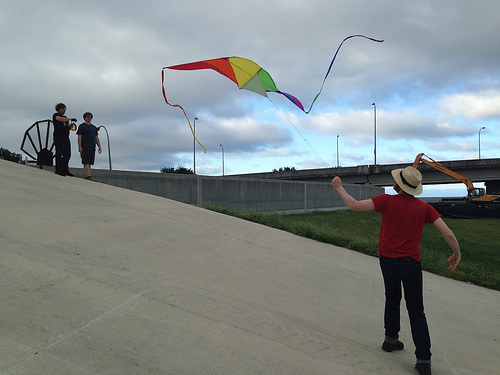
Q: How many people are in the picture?
A: 3.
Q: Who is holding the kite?
A: Man.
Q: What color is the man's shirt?
A: Red.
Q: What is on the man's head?
A: Hat.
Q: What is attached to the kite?
A: String.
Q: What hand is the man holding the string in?
A: Left.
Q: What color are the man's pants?
A: Black.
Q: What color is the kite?
A: Red, yellow and green.